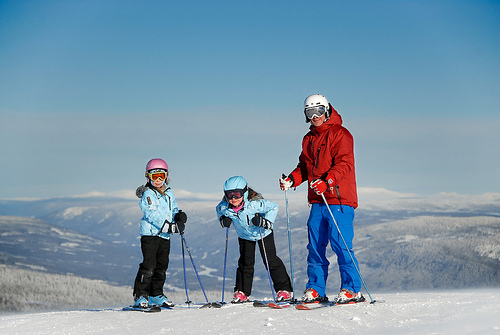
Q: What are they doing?
A: Standing.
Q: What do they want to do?
A: Sport.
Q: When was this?
A: Daytime.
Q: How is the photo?
A: Clear.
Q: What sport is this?
A: Ice skating.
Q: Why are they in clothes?
A: To keep warm.